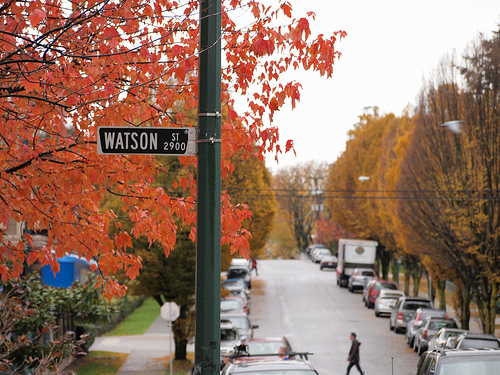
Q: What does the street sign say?
A: Watson St.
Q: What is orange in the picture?
A: Tree leaves.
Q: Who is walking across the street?
A: A man.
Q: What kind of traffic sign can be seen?
A: A stop sign.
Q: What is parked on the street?
A: Cars and trucks.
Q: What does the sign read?
A: WATSON ST.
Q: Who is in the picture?
A: A man.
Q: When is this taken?
A: Fall.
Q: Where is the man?
A: On the road.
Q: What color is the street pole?
A: Green.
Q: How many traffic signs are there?
A: One.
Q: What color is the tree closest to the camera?
A: Red.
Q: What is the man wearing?
A: A hoodie.